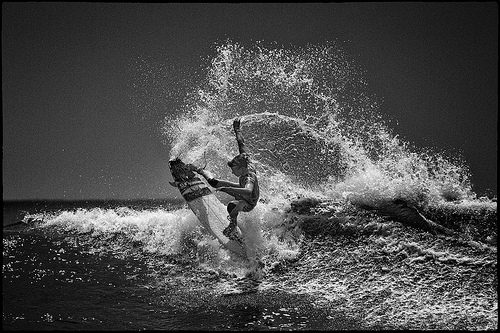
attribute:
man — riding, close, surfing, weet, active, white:
[216, 138, 266, 236]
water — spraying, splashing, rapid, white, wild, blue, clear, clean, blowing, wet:
[42, 226, 186, 327]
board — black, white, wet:
[167, 151, 230, 250]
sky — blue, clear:
[47, 12, 161, 80]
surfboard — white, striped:
[166, 154, 249, 264]